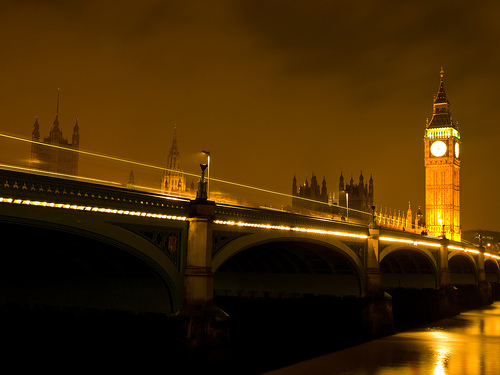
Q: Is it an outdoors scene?
A: Yes, it is outdoors.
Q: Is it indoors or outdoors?
A: It is outdoors.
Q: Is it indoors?
A: No, it is outdoors.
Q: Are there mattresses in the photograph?
A: No, there are no mattresses.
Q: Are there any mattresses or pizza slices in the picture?
A: No, there are no mattresses or pizza slices.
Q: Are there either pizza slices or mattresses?
A: No, there are no mattresses or pizza slices.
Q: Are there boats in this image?
A: No, there are no boats.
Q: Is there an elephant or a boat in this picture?
A: No, there are no boats or elephants.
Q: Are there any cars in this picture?
A: No, there are no cars.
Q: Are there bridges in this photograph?
A: Yes, there is a bridge.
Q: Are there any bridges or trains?
A: Yes, there is a bridge.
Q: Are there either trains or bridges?
A: Yes, there is a bridge.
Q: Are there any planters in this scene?
A: No, there are no planters.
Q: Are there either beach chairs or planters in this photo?
A: No, there are no planters or beach chairs.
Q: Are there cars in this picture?
A: No, there are no cars.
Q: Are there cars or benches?
A: No, there are no cars or benches.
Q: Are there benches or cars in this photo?
A: No, there are no cars or benches.